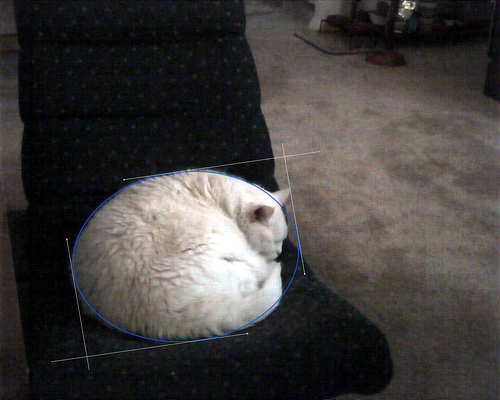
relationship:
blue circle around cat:
[71, 170, 290, 343] [35, 140, 318, 350]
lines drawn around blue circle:
[49, 142, 320, 368] [71, 170, 290, 343]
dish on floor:
[367, 52, 410, 66] [0, 0, 500, 397]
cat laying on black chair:
[71, 169, 290, 339] [14, 0, 395, 400]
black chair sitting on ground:
[14, 0, 395, 400] [348, 128, 470, 240]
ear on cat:
[243, 200, 280, 224] [71, 169, 290, 339]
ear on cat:
[272, 189, 289, 205] [71, 169, 290, 339]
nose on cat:
[273, 239, 295, 266] [71, 169, 290, 339]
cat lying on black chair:
[71, 169, 290, 339] [14, 0, 395, 400]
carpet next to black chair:
[3, 1, 498, 397] [14, 0, 395, 400]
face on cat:
[263, 219, 295, 261] [71, 169, 290, 339]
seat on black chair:
[38, 250, 385, 392] [14, 0, 395, 400]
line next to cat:
[281, 138, 309, 283] [71, 169, 290, 339]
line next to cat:
[113, 147, 325, 179] [71, 169, 290, 339]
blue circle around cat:
[71, 170, 290, 343] [71, 169, 290, 339]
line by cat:
[64, 239, 92, 371] [71, 169, 290, 339]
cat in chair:
[71, 169, 290, 339] [319, 12, 384, 49]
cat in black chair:
[71, 169, 290, 339] [14, 0, 395, 400]